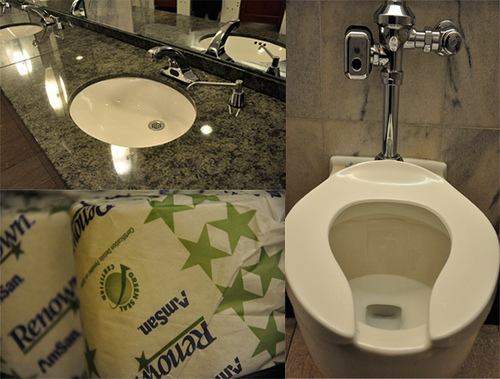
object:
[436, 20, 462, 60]
lever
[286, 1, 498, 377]
toilet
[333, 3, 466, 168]
valve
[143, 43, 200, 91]
faucet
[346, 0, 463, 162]
silver plumbing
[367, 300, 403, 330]
water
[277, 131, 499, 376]
toilet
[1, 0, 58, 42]
sink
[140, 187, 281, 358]
stars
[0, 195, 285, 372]
rolls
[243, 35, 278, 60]
holes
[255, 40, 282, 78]
soap pump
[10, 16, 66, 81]
reflection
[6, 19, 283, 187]
marble countertop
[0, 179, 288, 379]
toilet paper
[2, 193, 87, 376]
toilet paper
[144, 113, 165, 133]
drain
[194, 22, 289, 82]
sink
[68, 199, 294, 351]
toilet paper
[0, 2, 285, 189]
countertop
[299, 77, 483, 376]
toilet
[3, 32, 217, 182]
lighting reflection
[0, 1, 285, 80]
mirror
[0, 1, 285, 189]
sink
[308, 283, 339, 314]
seat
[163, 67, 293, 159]
pump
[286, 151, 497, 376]
toilet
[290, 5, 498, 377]
bathroom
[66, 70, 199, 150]
sink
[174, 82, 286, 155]
countertop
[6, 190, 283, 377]
tissue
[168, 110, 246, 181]
reflection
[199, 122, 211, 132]
light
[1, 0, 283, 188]
counter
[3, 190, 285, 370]
wrapping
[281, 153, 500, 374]
seat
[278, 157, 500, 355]
toilet